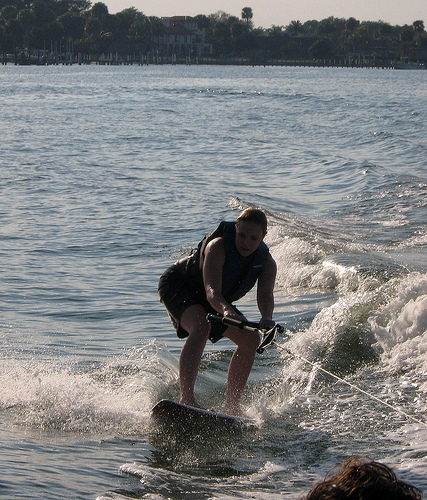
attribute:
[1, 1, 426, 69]
leaves — green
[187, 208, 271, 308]
vest — life vest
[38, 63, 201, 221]
water — calm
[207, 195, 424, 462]
wave — small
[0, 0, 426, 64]
trees — some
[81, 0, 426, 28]
sky — full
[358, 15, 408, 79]
tree — tall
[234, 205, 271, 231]
hair — person's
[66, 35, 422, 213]
water — some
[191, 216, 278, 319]
vest — black, life